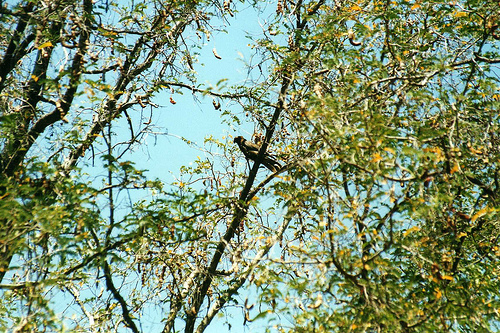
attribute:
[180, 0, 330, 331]
long branch — tree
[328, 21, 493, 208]
trees — green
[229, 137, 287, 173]
bird — Black 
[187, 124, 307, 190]
bird — Black 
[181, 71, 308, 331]
branch — long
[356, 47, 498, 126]
long branch — tree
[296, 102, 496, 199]
long branch — tree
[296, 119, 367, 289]
long branch — tree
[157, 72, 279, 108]
long branch — tree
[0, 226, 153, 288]
long branch — tree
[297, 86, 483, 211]
branch — long 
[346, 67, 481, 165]
leaves — green 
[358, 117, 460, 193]
leaves — white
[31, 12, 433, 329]
trees — green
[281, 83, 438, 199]
leaves — green 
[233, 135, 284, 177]
bird — black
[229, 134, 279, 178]
bird — Black 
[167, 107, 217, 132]
sky — clear, blue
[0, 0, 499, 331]
leaves — orange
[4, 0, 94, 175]
branch — long 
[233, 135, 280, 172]
bird — small 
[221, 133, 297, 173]
bird — Black 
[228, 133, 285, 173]
bird — Black 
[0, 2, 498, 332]
sky — cloudy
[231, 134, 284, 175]
bird — standing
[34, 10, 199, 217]
tree — green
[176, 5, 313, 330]
tree branch — long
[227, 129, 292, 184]
bird — small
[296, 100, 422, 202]
leaves — green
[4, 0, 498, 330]
trees — green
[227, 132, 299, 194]
bird — black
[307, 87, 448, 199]
leaves — orange